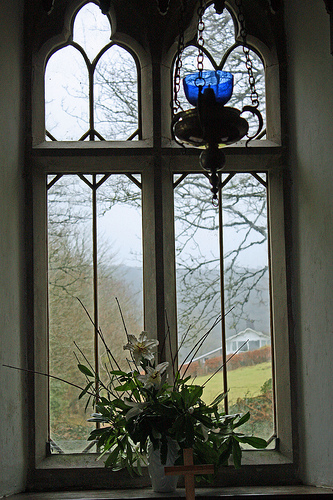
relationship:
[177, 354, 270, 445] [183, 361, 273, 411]
hill has grass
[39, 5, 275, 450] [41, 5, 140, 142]
window has a top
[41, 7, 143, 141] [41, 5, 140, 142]
window has a top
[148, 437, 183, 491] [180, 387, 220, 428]
vase has leaves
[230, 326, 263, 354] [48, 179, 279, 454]
house in background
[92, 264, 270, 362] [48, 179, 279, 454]
mountains are in background